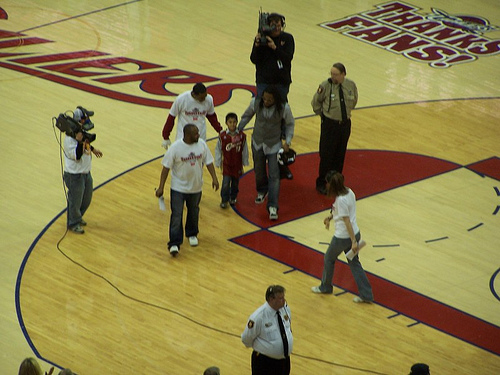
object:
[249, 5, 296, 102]
camerman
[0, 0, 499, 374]
scene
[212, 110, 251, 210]
boy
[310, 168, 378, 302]
woman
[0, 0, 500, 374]
court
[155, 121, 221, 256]
man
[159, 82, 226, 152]
man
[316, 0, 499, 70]
writing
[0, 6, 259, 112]
logo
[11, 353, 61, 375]
woman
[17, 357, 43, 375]
head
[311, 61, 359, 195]
officer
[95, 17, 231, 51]
part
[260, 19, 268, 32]
part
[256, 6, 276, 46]
camera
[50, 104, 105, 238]
camerman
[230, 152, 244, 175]
red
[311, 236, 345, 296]
left leg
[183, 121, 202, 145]
head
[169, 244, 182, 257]
shoe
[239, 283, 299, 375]
security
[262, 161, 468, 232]
line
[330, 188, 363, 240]
shirt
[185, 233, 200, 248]
shoes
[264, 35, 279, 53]
hand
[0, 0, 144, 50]
three point line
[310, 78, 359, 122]
shirt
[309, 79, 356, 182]
uniform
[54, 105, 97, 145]
camera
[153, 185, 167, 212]
paper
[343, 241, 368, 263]
paper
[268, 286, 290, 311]
headphone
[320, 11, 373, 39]
frame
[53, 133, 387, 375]
cord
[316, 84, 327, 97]
emblem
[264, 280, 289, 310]
head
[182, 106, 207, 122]
symbol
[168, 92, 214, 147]
shirt